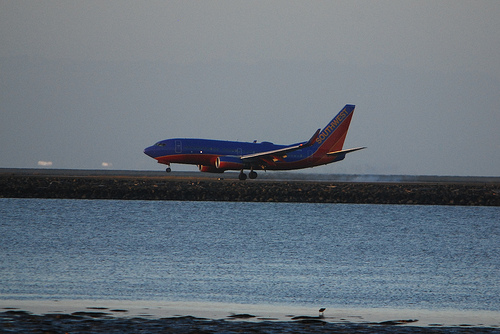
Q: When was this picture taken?
A: Evening.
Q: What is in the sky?
A: A plane.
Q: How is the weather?
A: Clear.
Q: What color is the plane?
A: Orange and blue.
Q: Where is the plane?
A: The sky.